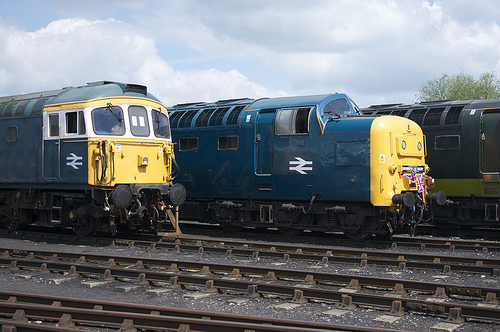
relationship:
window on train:
[275, 106, 312, 134] [161, 90, 453, 248]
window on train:
[220, 137, 237, 148] [161, 90, 453, 248]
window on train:
[92, 105, 124, 132] [1, 81, 187, 242]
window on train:
[65, 111, 77, 132] [1, 81, 187, 242]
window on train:
[47, 111, 58, 135] [1, 81, 187, 242]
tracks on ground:
[3, 287, 390, 329] [2, 227, 499, 328]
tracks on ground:
[1, 244, 499, 325] [2, 227, 499, 328]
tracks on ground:
[1, 222, 499, 279] [2, 227, 499, 328]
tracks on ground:
[383, 232, 498, 249] [2, 227, 499, 328]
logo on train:
[66, 153, 83, 170] [1, 81, 187, 242]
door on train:
[479, 107, 497, 174] [353, 99, 498, 229]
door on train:
[253, 110, 274, 175] [161, 90, 453, 248]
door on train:
[38, 106, 65, 183] [1, 81, 187, 242]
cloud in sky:
[0, 11, 277, 96] [0, 0, 495, 79]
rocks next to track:
[268, 261, 365, 289] [242, 225, 379, 287]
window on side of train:
[275, 105, 310, 135] [1, 81, 187, 242]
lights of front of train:
[414, 140, 422, 152] [166, 91, 433, 241]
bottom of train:
[188, 200, 409, 247] [175, 97, 443, 244]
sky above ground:
[0, 2, 499, 106] [2, 220, 499, 332]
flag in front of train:
[411, 169, 431, 209] [166, 91, 433, 241]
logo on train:
[285, 155, 315, 175] [166, 91, 433, 241]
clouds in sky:
[0, 0, 500, 105] [0, 2, 499, 106]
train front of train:
[41, 79, 183, 234] [1, 81, 187, 242]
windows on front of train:
[87, 103, 173, 144] [1, 81, 187, 242]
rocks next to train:
[162, 288, 266, 317] [175, 97, 443, 244]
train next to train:
[166, 91, 433, 241] [361, 97, 499, 239]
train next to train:
[1, 81, 187, 242] [166, 91, 433, 241]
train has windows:
[0, 80, 187, 238] [274, 103, 315, 136]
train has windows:
[164, 91, 446, 241] [168, 104, 245, 131]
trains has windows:
[361, 97, 499, 235] [367, 103, 469, 133]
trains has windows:
[361, 97, 499, 235] [2, 92, 51, 116]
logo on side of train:
[65, 150, 84, 170] [1, 81, 187, 242]